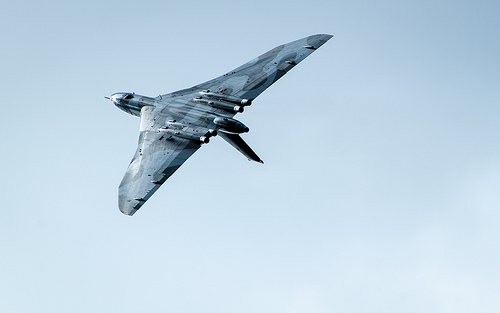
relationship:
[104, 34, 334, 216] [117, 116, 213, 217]
airplane has wing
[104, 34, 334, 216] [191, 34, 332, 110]
airplane has wing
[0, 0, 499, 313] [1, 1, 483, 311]
background seen in background